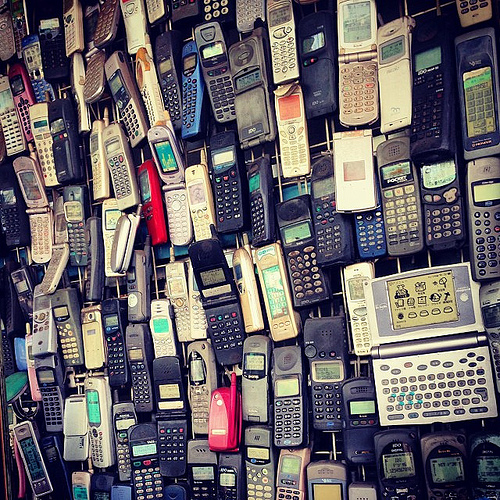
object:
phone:
[146, 125, 191, 248]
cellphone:
[246, 159, 273, 247]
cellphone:
[329, 126, 379, 216]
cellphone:
[340, 374, 381, 467]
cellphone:
[208, 373, 242, 455]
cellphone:
[183, 150, 214, 241]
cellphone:
[335, 0, 377, 127]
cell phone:
[209, 124, 246, 234]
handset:
[174, 41, 210, 142]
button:
[192, 79, 197, 84]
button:
[187, 78, 191, 83]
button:
[192, 102, 196, 107]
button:
[190, 114, 194, 119]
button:
[186, 110, 190, 115]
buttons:
[215, 171, 240, 222]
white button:
[216, 400, 222, 406]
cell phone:
[61, 186, 89, 269]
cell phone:
[245, 152, 277, 246]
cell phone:
[126, 422, 166, 499]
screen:
[274, 92, 308, 119]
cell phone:
[7, 419, 54, 497]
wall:
[2, 4, 498, 499]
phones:
[464, 431, 500, 500]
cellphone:
[24, 321, 44, 402]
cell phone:
[373, 420, 422, 500]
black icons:
[394, 276, 455, 322]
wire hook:
[214, 27, 234, 37]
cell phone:
[181, 35, 207, 140]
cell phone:
[273, 194, 330, 310]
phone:
[177, 77, 207, 143]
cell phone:
[183, 148, 217, 240]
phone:
[78, 374, 111, 466]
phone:
[146, 298, 175, 357]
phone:
[186, 338, 216, 435]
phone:
[188, 436, 216, 499]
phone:
[241, 336, 272, 425]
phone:
[237, 335, 268, 423]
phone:
[211, 453, 245, 499]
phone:
[305, 461, 346, 497]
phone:
[134, 158, 169, 245]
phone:
[231, 77, 277, 149]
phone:
[344, 259, 378, 357]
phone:
[190, 265, 210, 339]